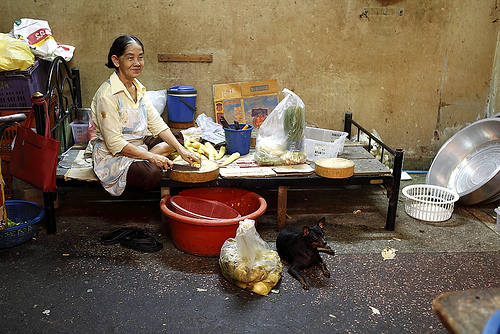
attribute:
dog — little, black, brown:
[276, 211, 336, 290]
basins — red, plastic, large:
[160, 185, 272, 255]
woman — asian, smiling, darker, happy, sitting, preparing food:
[88, 32, 205, 198]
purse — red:
[7, 101, 62, 192]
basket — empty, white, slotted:
[401, 181, 460, 224]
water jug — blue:
[167, 82, 199, 125]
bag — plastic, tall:
[252, 86, 308, 166]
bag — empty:
[12, 14, 76, 63]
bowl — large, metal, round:
[424, 115, 500, 207]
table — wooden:
[47, 135, 393, 176]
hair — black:
[104, 32, 146, 71]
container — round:
[1, 196, 47, 245]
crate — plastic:
[69, 117, 90, 144]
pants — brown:
[125, 126, 187, 191]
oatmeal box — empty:
[212, 80, 281, 147]